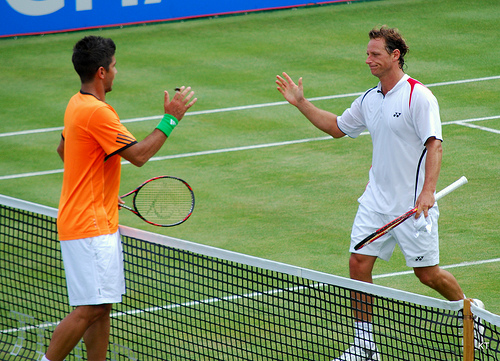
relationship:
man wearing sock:
[268, 22, 493, 359] [347, 315, 377, 343]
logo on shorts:
[411, 252, 428, 267] [334, 195, 451, 268]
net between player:
[0, 196, 499, 361] [37, 36, 197, 359]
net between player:
[0, 196, 499, 361] [276, 26, 485, 359]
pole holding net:
[434, 286, 497, 359] [0, 196, 499, 361]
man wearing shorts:
[274, 22, 484, 360] [349, 202, 440, 267]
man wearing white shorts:
[49, 34, 199, 344] [55, 233, 126, 308]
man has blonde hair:
[274, 22, 484, 360] [361, 21, 421, 67]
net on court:
[163, 246, 315, 353] [0, 2, 498, 354]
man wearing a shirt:
[274, 22, 484, 360] [349, 80, 473, 190]